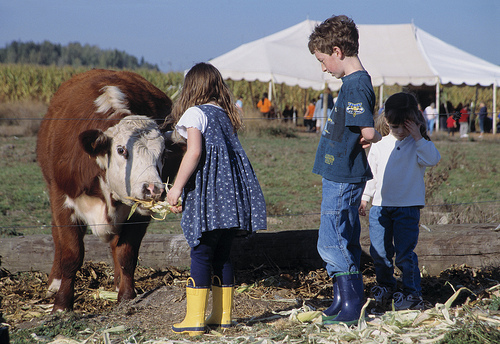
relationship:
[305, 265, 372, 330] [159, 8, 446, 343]
boots on kids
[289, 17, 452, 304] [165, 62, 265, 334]
two boys behind girl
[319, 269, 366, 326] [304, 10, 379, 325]
boots on boy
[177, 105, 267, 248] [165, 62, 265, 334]
dress on girl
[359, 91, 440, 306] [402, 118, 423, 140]
boy with hand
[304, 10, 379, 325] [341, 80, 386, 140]
boy with arm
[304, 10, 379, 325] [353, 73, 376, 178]
boy with back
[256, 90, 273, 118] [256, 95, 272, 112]
person wearing shirt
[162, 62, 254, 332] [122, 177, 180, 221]
girl giving corn husks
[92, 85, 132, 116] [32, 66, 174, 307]
spot on cow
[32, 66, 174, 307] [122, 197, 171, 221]
cow eating corn husks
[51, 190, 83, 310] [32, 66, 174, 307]
leg of cow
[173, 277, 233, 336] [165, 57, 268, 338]
boots on kid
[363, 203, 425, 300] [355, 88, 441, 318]
jeans on kid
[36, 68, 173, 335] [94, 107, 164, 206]
cow with face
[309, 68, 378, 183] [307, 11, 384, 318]
t-shirt on boy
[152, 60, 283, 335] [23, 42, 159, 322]
girl feeds cow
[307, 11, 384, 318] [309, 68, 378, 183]
boy has on a t-shirt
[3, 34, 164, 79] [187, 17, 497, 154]
treeline in fair area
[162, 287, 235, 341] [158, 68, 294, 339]
boots on girl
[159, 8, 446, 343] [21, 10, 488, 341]
kids on farm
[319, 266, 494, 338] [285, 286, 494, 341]
corn husks in pile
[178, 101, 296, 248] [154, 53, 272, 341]
dress on girl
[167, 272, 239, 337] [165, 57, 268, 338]
boots on kid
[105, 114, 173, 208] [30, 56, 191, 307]
face on cow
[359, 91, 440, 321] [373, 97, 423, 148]
boy covering face